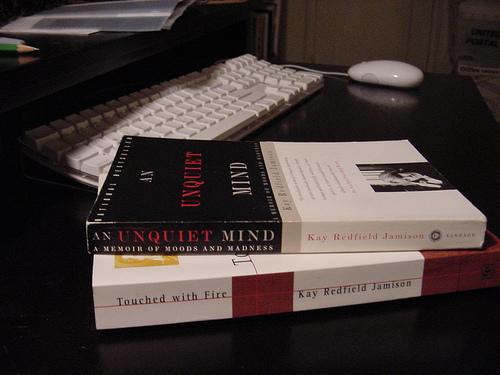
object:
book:
[85, 135, 488, 256]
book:
[87, 248, 499, 330]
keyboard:
[12, 52, 325, 190]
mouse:
[348, 57, 425, 90]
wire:
[279, 62, 347, 78]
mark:
[112, 250, 181, 267]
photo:
[355, 163, 455, 194]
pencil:
[0, 41, 39, 54]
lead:
[32, 46, 39, 53]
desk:
[1, 58, 499, 374]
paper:
[1, 0, 203, 36]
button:
[22, 123, 60, 148]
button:
[43, 136, 80, 153]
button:
[62, 143, 93, 161]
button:
[81, 154, 111, 174]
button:
[54, 117, 81, 135]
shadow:
[14, 65, 220, 184]